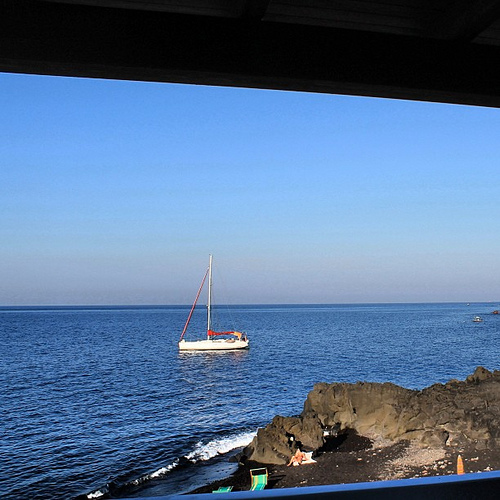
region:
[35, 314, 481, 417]
a body of water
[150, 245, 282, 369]
a boat in the water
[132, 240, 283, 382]
a sailboat with mast down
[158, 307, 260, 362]
white sail boat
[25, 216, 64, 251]
white clouds in blue sky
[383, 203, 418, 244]
white clouds in blue sky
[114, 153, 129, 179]
white clouds in blue sky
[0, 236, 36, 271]
white clouds in blue sky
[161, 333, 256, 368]
white sail boat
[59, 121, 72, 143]
white clouds in blue sky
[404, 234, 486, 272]
white clouds in blue sky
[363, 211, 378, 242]
white clouds in blue sky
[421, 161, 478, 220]
white clouds in blue sky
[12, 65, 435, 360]
a clear blue sky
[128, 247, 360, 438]
a sailboat on the water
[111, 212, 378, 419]
a boat on the water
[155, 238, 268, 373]
a white sailboat on the water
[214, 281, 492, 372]
a body of water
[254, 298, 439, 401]
a body of blue water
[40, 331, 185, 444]
the water is calm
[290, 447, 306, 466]
person on the towel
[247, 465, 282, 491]
beach chair on the soil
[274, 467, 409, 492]
the soil is black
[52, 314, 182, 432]
boat in the water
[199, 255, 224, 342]
pole on the boat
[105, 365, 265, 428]
ripples in the water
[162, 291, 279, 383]
white boat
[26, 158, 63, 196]
white clouds in blue sky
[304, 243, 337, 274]
white clouds in blue sky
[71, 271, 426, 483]
this is a bay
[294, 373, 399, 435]
the rocks are brown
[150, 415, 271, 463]
the waves are crashing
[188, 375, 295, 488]
the waves are white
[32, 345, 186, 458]
the water is blue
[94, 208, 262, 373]
the boat is white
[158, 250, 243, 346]
the mast is tall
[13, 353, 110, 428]
Large body of water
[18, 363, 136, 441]
Large body of blue water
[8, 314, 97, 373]
Large body of water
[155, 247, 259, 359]
Boat in an ocean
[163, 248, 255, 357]
White boat in an ocean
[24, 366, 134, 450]
Ripples in the water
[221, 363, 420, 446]
Rocks near an ocean